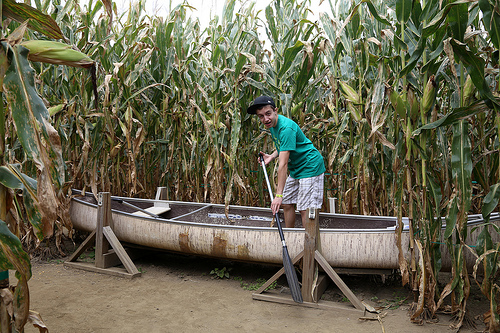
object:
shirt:
[271, 116, 326, 178]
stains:
[177, 230, 252, 257]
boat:
[68, 187, 498, 269]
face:
[255, 107, 280, 124]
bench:
[130, 202, 172, 216]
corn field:
[1, 0, 500, 333]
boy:
[245, 97, 324, 230]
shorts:
[277, 175, 327, 211]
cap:
[246, 96, 275, 110]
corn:
[13, 40, 94, 68]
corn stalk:
[3, 0, 99, 332]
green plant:
[212, 266, 235, 279]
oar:
[258, 152, 301, 304]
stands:
[62, 193, 138, 281]